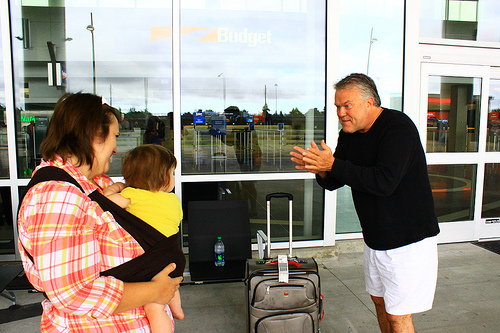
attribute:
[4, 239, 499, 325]
cement floor — Grey 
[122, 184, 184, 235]
shirt — yellow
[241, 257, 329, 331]
luggage — black, gray 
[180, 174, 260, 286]
bag — black, luggage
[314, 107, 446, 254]
shirt — black, long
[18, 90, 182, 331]
woman — old 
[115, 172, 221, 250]
shirt — yellow 